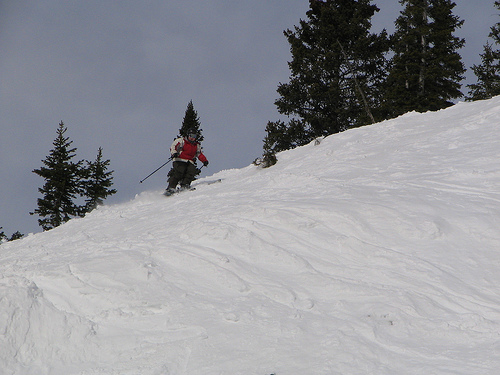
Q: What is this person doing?
A: Skiing.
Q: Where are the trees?
A: Behind skier.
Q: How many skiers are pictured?
A: 1.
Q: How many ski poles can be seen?
A: 2.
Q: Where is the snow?
A: On the ski hill.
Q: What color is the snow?
A: White.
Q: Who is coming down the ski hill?
A: Skier.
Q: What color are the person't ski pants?
A: Black.